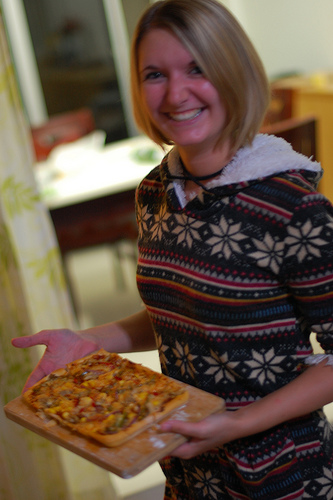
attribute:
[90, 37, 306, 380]
woman — visibely, blonde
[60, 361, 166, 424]
pizza — rectangular, square, home made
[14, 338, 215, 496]
tray — brown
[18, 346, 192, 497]
board — wooden, wood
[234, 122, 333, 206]
hood — fuzzy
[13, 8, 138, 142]
doorway — open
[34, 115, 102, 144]
chair — wooden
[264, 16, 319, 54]
wall — white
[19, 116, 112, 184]
chairs — sitting